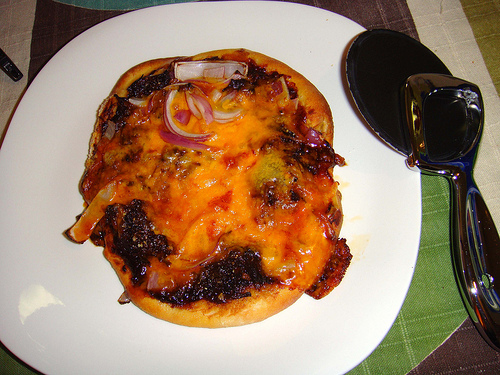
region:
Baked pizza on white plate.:
[1, 0, 419, 373]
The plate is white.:
[3, 144, 80, 206]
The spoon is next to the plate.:
[338, 22, 498, 349]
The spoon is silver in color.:
[338, 25, 498, 360]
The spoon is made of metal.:
[341, 17, 498, 349]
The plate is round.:
[3, 3, 437, 373]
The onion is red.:
[158, 82, 215, 149]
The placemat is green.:
[413, 307, 447, 344]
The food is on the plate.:
[70, 51, 352, 330]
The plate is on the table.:
[1, 2, 498, 373]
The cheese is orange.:
[186, 186, 240, 211]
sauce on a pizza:
[198, 227, 253, 254]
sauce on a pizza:
[275, 216, 311, 241]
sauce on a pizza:
[215, 169, 249, 204]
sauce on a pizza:
[161, 142, 193, 171]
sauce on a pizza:
[134, 130, 159, 147]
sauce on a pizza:
[260, 92, 300, 130]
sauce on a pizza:
[151, 210, 193, 265]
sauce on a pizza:
[122, 165, 155, 203]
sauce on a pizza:
[105, 165, 125, 197]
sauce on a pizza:
[100, 182, 120, 209]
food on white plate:
[61, 46, 360, 335]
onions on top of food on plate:
[145, 66, 230, 154]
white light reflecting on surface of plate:
[9, 273, 74, 327]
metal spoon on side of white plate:
[339, 18, 493, 357]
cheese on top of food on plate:
[129, 79, 330, 290]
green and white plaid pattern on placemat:
[365, 179, 480, 371]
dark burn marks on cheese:
[104, 204, 173, 276]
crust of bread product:
[151, 297, 271, 331]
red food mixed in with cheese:
[208, 178, 245, 218]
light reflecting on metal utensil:
[463, 272, 480, 308]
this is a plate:
[0, 22, 455, 369]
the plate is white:
[16, 19, 458, 359]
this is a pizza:
[46, 36, 377, 333]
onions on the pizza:
[153, 71, 265, 156]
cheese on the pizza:
[115, 121, 310, 270]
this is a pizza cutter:
[329, 10, 494, 289]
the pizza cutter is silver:
[343, 16, 493, 283]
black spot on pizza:
[173, 253, 271, 300]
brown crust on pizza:
[153, 293, 307, 341]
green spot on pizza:
[245, 127, 307, 207]